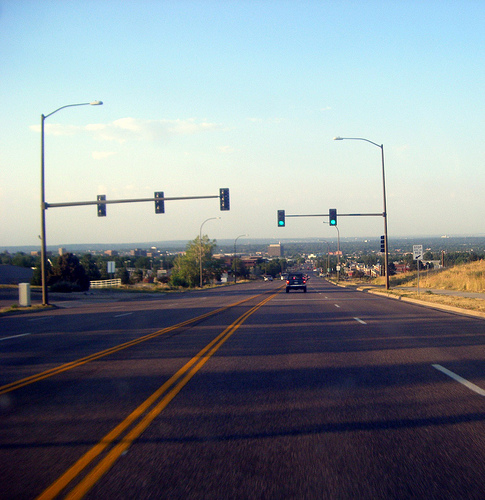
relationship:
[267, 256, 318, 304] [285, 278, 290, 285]
suv with taillight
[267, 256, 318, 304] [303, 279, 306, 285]
suv with taillight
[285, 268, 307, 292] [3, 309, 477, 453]
car on road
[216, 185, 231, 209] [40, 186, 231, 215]
light on pole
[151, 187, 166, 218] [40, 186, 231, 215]
light on pole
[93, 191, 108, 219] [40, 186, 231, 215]
light on pole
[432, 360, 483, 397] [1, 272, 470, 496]
stripes on street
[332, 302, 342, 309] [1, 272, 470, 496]
stripes on street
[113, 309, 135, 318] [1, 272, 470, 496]
stripes on street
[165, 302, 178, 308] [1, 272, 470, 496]
stripes on street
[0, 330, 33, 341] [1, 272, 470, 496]
stripes on street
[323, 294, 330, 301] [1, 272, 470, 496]
stripes on street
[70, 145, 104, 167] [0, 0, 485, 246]
clouds in sky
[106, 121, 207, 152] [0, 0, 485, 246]
clouds in sky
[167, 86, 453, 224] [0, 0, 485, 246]
clouds in sky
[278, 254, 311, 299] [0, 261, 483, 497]
vehicle on road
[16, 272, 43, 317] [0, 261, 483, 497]
white object on road